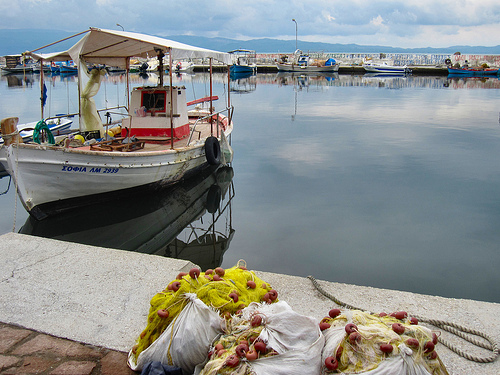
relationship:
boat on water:
[0, 25, 237, 223] [2, 66, 499, 299]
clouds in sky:
[223, 0, 398, 38] [0, 1, 485, 61]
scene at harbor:
[13, 31, 490, 278] [4, 6, 491, 364]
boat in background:
[0, 25, 237, 223] [3, 6, 499, 107]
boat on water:
[0, 25, 237, 223] [6, 7, 499, 257]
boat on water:
[0, 25, 237, 223] [270, 88, 465, 263]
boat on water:
[357, 59, 409, 76] [270, 88, 465, 263]